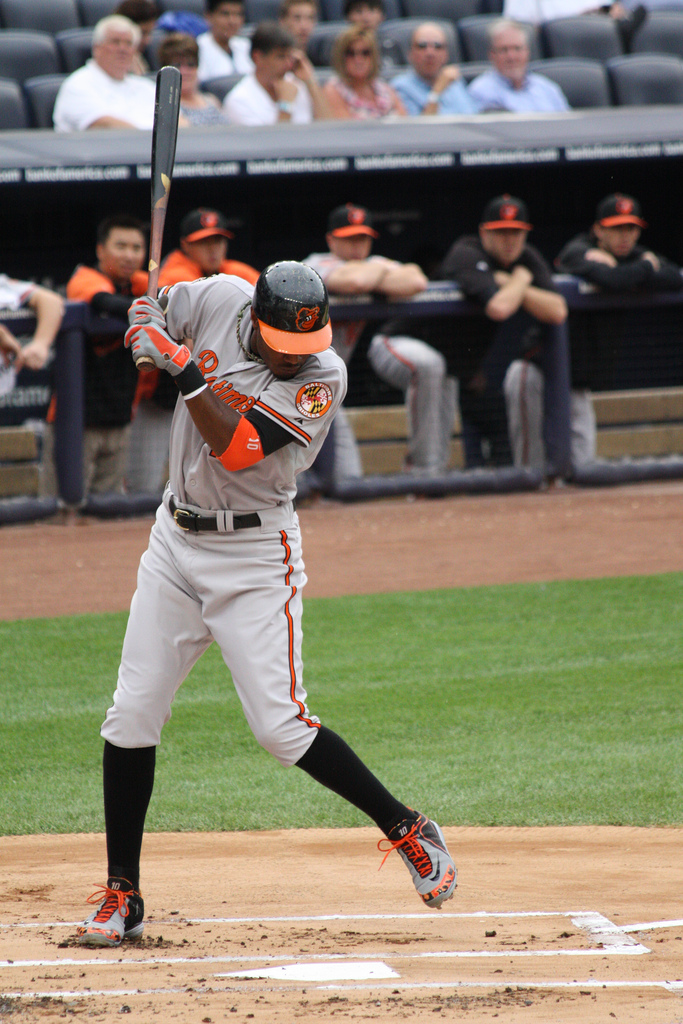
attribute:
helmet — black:
[251, 259, 334, 357]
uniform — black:
[444, 235, 580, 470]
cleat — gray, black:
[384, 803, 464, 912]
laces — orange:
[371, 818, 433, 878]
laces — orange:
[87, 879, 139, 923]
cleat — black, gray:
[68, 875, 147, 953]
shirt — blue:
[389, 60, 478, 120]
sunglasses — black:
[409, 40, 447, 52]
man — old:
[46, 16, 186, 130]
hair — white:
[92, 9, 141, 49]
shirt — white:
[46, 53, 177, 129]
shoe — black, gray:
[81, 880, 145, 948]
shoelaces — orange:
[81, 880, 136, 928]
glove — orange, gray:
[124, 325, 197, 380]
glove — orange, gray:
[123, 294, 167, 343]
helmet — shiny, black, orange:
[253, 257, 338, 362]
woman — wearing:
[319, 78, 395, 152]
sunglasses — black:
[342, 139, 365, 156]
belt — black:
[152, 481, 287, 549]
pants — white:
[99, 483, 336, 756]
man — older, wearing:
[93, 249, 377, 758]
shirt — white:
[122, 273, 365, 554]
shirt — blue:
[159, 259, 352, 537]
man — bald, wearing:
[67, 253, 469, 978]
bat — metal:
[124, 68, 212, 374]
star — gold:
[140, 167, 177, 206]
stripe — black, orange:
[262, 521, 338, 738]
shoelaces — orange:
[73, 879, 131, 931]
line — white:
[0, 901, 607, 928]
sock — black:
[87, 736, 161, 888]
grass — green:
[22, 562, 681, 863]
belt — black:
[150, 485, 265, 571]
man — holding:
[55, 244, 467, 842]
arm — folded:
[144, 331, 352, 492]